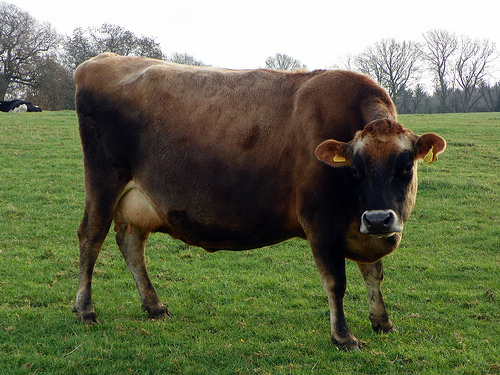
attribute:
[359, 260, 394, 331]
leg — dark brown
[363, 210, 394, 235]
nose — black, large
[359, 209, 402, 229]
nose — large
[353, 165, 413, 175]
eyes — open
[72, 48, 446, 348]
cow — brown, black, dark brown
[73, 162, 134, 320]
leg — dark brown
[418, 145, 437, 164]
tag — ID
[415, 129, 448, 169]
ear — cows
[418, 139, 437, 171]
tag — yellow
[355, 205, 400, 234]
snout — white, black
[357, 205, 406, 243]
snout — black, white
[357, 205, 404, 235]
snout — white, black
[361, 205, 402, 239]
snout — black, white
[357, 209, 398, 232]
snout — black, white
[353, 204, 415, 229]
snout — white, black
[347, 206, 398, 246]
snout — white, black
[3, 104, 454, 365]
pasture — green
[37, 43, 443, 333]
cow — fat, brown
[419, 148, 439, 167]
tag — yellow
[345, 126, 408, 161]
spots — white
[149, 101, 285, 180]
spots — small, dark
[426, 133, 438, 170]
tag — yellow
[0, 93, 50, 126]
car — black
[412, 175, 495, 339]
grass — dark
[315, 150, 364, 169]
tag — yellow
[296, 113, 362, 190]
cows ear — brown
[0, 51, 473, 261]
cow — brown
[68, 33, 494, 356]
cow — brown